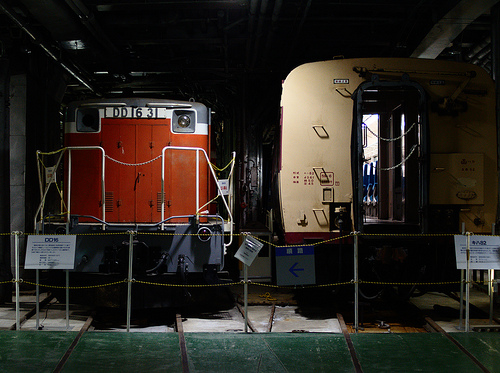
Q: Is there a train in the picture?
A: Yes, there is a train.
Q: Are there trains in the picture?
A: Yes, there is a train.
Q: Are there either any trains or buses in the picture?
A: Yes, there is a train.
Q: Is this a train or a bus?
A: This is a train.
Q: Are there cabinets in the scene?
A: No, there are no cabinets.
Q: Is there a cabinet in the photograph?
A: No, there are no cabinets.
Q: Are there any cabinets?
A: No, there are no cabinets.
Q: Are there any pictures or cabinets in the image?
A: No, there are no cabinets or pictures.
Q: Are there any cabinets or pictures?
A: No, there are no cabinets or pictures.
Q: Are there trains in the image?
A: Yes, there is a train.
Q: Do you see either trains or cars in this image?
A: Yes, there is a train.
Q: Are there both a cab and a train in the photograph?
A: No, there is a train but no taxis.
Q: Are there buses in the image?
A: No, there are no buses.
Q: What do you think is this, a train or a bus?
A: This is a train.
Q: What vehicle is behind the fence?
A: The vehicle is a train.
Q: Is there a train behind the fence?
A: Yes, there is a train behind the fence.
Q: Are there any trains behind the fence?
A: Yes, there is a train behind the fence.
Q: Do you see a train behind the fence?
A: Yes, there is a train behind the fence.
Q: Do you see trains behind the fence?
A: Yes, there is a train behind the fence.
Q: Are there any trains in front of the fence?
A: No, the train is behind the fence.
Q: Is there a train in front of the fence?
A: No, the train is behind the fence.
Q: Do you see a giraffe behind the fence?
A: No, there is a train behind the fence.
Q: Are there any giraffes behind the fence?
A: No, there is a train behind the fence.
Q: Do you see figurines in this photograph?
A: No, there are no figurines.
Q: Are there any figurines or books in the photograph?
A: No, there are no figurines or books.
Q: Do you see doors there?
A: Yes, there is a door.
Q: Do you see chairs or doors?
A: Yes, there is a door.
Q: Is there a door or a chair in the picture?
A: Yes, there is a door.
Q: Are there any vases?
A: No, there are no vases.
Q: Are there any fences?
A: Yes, there is a fence.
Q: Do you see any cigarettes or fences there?
A: Yes, there is a fence.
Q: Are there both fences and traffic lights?
A: No, there is a fence but no traffic lights.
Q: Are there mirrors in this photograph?
A: No, there are no mirrors.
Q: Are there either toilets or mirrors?
A: No, there are no mirrors or toilets.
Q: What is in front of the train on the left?
A: The fence is in front of the train.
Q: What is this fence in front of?
A: The fence is in front of the train.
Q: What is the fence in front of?
A: The fence is in front of the train.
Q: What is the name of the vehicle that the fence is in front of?
A: The vehicle is a train.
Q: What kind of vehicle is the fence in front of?
A: The fence is in front of the train.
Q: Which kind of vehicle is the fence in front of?
A: The fence is in front of the train.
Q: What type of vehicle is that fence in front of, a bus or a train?
A: The fence is in front of a train.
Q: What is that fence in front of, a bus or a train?
A: The fence is in front of a train.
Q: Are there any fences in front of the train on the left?
A: Yes, there is a fence in front of the train.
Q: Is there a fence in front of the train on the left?
A: Yes, there is a fence in front of the train.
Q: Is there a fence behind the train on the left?
A: No, the fence is in front of the train.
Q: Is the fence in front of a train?
A: Yes, the fence is in front of a train.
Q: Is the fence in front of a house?
A: No, the fence is in front of a train.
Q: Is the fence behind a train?
A: No, the fence is in front of a train.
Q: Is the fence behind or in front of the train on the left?
A: The fence is in front of the train.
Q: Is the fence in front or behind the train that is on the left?
A: The fence is in front of the train.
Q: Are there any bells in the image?
A: No, there are no bells.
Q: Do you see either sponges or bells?
A: No, there are no bells or sponges.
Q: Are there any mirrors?
A: No, there are no mirrors.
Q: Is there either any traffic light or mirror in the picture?
A: No, there are no mirrors or traffic lights.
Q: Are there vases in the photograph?
A: No, there are no vases.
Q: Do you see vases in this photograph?
A: No, there are no vases.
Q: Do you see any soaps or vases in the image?
A: No, there are no vases or soaps.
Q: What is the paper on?
A: The paper is on the chain.